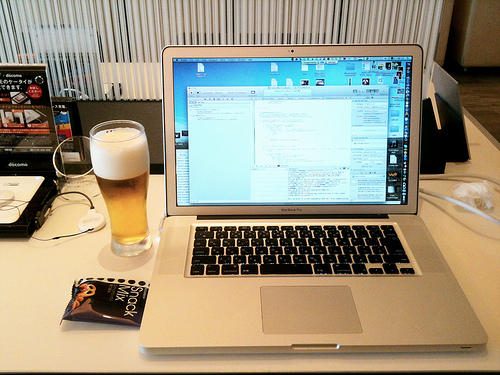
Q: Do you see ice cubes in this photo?
A: No, there are no ice cubes.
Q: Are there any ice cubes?
A: No, there are no ice cubes.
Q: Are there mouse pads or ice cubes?
A: No, there are no ice cubes or mouse pads.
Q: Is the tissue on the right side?
A: Yes, the tissue is on the right of the image.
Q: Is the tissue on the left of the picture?
A: No, the tissue is on the right of the image.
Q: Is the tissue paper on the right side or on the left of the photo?
A: The tissue paper is on the right of the image.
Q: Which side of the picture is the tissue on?
A: The tissue is on the right of the image.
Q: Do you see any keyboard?
A: Yes, there is a keyboard.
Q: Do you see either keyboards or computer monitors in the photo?
A: Yes, there is a keyboard.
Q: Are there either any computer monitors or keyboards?
A: Yes, there is a keyboard.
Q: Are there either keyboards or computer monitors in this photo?
A: Yes, there is a keyboard.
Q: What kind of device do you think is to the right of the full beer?
A: The device is a keyboard.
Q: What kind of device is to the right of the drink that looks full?
A: The device is a keyboard.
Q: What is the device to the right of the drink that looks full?
A: The device is a keyboard.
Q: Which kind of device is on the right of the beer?
A: The device is a keyboard.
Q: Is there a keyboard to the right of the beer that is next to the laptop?
A: Yes, there is a keyboard to the right of the beer.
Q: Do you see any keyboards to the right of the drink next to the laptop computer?
A: Yes, there is a keyboard to the right of the beer.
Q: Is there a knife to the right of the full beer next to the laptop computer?
A: No, there is a keyboard to the right of the beer.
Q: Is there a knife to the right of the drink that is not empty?
A: No, there is a keyboard to the right of the beer.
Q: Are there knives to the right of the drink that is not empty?
A: No, there is a keyboard to the right of the beer.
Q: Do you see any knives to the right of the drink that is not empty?
A: No, there is a keyboard to the right of the beer.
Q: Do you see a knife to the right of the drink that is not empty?
A: No, there is a keyboard to the right of the beer.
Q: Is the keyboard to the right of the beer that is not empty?
A: Yes, the keyboard is to the right of the beer.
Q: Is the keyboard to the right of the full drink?
A: Yes, the keyboard is to the right of the beer.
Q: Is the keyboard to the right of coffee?
A: No, the keyboard is to the right of the beer.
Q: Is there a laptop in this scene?
A: Yes, there is a laptop.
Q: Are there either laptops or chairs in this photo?
A: Yes, there is a laptop.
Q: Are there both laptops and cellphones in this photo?
A: No, there is a laptop but no cell phones.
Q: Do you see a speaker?
A: No, there are no speakers.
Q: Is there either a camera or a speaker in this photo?
A: No, there are no speakers or cameras.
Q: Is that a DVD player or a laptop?
A: That is a laptop.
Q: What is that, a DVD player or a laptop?
A: That is a laptop.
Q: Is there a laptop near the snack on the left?
A: Yes, there is a laptop near the snack.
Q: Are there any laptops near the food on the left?
A: Yes, there is a laptop near the snack.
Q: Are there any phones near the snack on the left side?
A: No, there is a laptop near the snack.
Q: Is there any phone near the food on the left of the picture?
A: No, there is a laptop near the snack.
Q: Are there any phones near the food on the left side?
A: No, there is a laptop near the snack.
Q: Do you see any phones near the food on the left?
A: No, there is a laptop near the snack.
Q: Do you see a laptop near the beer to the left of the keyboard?
A: Yes, there is a laptop near the beer.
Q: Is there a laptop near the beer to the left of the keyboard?
A: Yes, there is a laptop near the beer.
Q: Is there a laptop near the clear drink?
A: Yes, there is a laptop near the beer.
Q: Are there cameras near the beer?
A: No, there is a laptop near the beer.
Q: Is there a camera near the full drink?
A: No, there is a laptop near the beer.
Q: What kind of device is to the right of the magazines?
A: The device is a laptop.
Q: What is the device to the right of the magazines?
A: The device is a laptop.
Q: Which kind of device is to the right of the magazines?
A: The device is a laptop.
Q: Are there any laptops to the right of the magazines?
A: Yes, there is a laptop to the right of the magazines.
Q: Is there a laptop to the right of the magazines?
A: Yes, there is a laptop to the right of the magazines.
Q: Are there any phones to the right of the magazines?
A: No, there is a laptop to the right of the magazines.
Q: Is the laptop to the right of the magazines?
A: Yes, the laptop is to the right of the magazines.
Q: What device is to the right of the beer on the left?
A: The device is a laptop.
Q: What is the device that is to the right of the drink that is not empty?
A: The device is a laptop.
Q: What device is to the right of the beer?
A: The device is a laptop.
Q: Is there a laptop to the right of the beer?
A: Yes, there is a laptop to the right of the beer.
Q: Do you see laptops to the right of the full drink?
A: Yes, there is a laptop to the right of the beer.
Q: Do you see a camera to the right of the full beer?
A: No, there is a laptop to the right of the beer.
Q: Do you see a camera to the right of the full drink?
A: No, there is a laptop to the right of the beer.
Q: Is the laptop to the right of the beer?
A: Yes, the laptop is to the right of the beer.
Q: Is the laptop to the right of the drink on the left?
A: Yes, the laptop is to the right of the beer.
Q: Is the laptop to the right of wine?
A: No, the laptop is to the right of the beer.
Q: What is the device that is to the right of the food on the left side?
A: The device is a laptop.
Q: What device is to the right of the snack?
A: The device is a laptop.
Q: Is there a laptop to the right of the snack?
A: Yes, there is a laptop to the right of the snack.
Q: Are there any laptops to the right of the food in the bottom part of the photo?
A: Yes, there is a laptop to the right of the snack.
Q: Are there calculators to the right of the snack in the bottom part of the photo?
A: No, there is a laptop to the right of the snack.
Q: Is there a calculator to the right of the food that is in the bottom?
A: No, there is a laptop to the right of the snack.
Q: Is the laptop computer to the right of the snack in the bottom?
A: Yes, the laptop computer is to the right of the snack.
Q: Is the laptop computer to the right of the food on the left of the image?
A: Yes, the laptop computer is to the right of the snack.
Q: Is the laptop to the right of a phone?
A: No, the laptop is to the right of the snack.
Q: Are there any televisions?
A: No, there are no televisions.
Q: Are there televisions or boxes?
A: No, there are no televisions or boxes.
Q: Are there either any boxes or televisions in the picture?
A: No, there are no televisions or boxes.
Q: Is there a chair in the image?
A: No, there are no chairs.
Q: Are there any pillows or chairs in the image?
A: No, there are no chairs or pillows.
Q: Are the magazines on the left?
A: Yes, the magazines are on the left of the image.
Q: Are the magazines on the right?
A: No, the magazines are on the left of the image.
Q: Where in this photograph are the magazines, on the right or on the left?
A: The magazines are on the left of the image.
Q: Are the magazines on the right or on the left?
A: The magazines are on the left of the image.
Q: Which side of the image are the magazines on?
A: The magazines are on the left of the image.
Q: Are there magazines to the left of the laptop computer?
A: Yes, there are magazines to the left of the laptop computer.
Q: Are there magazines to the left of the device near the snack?
A: Yes, there are magazines to the left of the laptop computer.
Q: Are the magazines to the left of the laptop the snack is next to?
A: Yes, the magazines are to the left of the laptop computer.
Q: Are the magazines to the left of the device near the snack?
A: Yes, the magazines are to the left of the laptop computer.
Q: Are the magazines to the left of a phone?
A: No, the magazines are to the left of the laptop computer.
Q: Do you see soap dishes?
A: No, there are no soap dishes.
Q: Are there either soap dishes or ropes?
A: No, there are no soap dishes or ropes.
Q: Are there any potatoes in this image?
A: No, there are no potatoes.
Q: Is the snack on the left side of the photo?
A: Yes, the snack is on the left of the image.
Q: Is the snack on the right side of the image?
A: No, the snack is on the left of the image.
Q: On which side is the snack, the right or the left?
A: The snack is on the left of the image.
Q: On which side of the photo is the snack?
A: The snack is on the left of the image.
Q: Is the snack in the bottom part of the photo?
A: Yes, the snack is in the bottom of the image.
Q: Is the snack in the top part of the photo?
A: No, the snack is in the bottom of the image.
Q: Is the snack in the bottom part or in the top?
A: The snack is in the bottom of the image.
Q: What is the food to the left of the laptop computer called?
A: The food is a snack.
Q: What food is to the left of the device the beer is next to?
A: The food is a snack.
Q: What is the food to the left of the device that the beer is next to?
A: The food is a snack.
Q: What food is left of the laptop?
A: The food is a snack.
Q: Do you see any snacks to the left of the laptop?
A: Yes, there is a snack to the left of the laptop.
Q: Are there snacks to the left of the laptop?
A: Yes, there is a snack to the left of the laptop.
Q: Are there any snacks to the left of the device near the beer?
A: Yes, there is a snack to the left of the laptop.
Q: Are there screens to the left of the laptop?
A: No, there is a snack to the left of the laptop.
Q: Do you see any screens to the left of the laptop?
A: No, there is a snack to the left of the laptop.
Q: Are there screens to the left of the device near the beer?
A: No, there is a snack to the left of the laptop.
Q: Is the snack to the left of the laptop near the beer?
A: Yes, the snack is to the left of the laptop computer.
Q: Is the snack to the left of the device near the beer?
A: Yes, the snack is to the left of the laptop computer.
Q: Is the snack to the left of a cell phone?
A: No, the snack is to the left of the laptop computer.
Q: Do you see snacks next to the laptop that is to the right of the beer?
A: Yes, there is a snack next to the laptop.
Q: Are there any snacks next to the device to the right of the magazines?
A: Yes, there is a snack next to the laptop.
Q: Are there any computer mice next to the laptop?
A: No, there is a snack next to the laptop.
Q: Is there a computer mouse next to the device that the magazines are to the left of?
A: No, there is a snack next to the laptop.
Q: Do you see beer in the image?
A: Yes, there is beer.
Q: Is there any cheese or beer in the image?
A: Yes, there is beer.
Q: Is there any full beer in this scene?
A: Yes, there is full beer.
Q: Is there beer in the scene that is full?
A: Yes, there is beer that is full.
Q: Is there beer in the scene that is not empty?
A: Yes, there is full beer.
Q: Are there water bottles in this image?
A: No, there are no water bottles.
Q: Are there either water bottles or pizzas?
A: No, there are no water bottles or pizzas.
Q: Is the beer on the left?
A: Yes, the beer is on the left of the image.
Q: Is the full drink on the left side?
A: Yes, the beer is on the left of the image.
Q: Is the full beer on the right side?
A: No, the beer is on the left of the image.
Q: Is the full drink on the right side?
A: No, the beer is on the left of the image.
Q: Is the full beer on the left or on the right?
A: The beer is on the left of the image.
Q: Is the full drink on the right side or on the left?
A: The beer is on the left of the image.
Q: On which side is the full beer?
A: The beer is on the left of the image.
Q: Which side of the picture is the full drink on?
A: The beer is on the left of the image.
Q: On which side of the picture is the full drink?
A: The beer is on the left of the image.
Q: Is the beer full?
A: Yes, the beer is full.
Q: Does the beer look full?
A: Yes, the beer is full.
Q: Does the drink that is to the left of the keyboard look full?
A: Yes, the beer is full.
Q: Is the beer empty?
A: No, the beer is full.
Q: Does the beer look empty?
A: No, the beer is full.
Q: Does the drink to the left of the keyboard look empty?
A: No, the beer is full.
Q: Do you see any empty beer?
A: No, there is beer but it is full.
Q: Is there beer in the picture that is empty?
A: No, there is beer but it is full.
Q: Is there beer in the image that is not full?
A: No, there is beer but it is full.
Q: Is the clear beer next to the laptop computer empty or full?
A: The beer is full.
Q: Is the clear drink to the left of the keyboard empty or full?
A: The beer is full.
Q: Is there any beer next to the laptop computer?
A: Yes, there is beer next to the laptop computer.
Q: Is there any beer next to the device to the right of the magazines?
A: Yes, there is beer next to the laptop computer.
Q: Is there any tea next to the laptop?
A: No, there is beer next to the laptop.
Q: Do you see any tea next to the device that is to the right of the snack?
A: No, there is beer next to the laptop.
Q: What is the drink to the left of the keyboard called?
A: The drink is beer.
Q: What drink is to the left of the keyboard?
A: The drink is beer.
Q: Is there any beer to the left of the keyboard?
A: Yes, there is beer to the left of the keyboard.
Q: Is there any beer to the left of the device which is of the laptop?
A: Yes, there is beer to the left of the keyboard.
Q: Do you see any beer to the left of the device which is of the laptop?
A: Yes, there is beer to the left of the keyboard.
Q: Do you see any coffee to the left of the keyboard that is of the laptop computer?
A: No, there is beer to the left of the keyboard.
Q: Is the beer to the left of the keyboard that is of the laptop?
A: Yes, the beer is to the left of the keyboard.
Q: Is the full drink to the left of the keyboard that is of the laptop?
A: Yes, the beer is to the left of the keyboard.